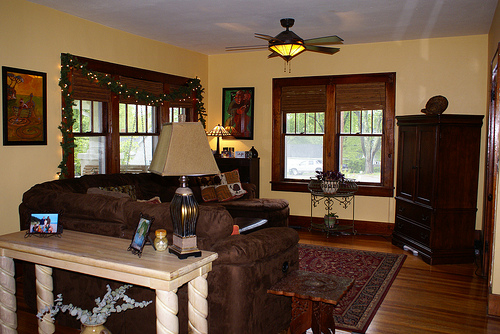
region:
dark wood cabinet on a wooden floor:
[394, 113, 483, 268]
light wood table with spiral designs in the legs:
[0, 215, 218, 332]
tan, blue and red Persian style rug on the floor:
[295, 240, 406, 331]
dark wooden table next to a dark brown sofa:
[264, 267, 355, 331]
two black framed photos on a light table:
[27, 210, 151, 257]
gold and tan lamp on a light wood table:
[148, 118, 222, 273]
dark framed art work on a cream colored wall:
[0, 62, 51, 148]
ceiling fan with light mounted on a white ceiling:
[221, 15, 345, 74]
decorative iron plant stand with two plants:
[309, 165, 358, 242]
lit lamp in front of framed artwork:
[205, 120, 232, 158]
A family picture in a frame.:
[26, 208, 65, 238]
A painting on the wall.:
[221, 85, 256, 141]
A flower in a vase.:
[36, 281, 153, 332]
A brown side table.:
[265, 265, 357, 332]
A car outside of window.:
[286, 153, 324, 177]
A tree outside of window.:
[354, 111, 381, 173]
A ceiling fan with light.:
[223, 15, 347, 72]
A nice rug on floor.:
[276, 242, 410, 332]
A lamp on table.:
[146, 120, 223, 260]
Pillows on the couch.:
[198, 166, 251, 202]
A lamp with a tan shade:
[148, 118, 219, 258]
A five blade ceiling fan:
[225, 18, 347, 71]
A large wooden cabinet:
[390, 108, 482, 268]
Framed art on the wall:
[217, 84, 257, 140]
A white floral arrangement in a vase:
[36, 282, 160, 332]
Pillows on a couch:
[193, 168, 251, 206]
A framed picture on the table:
[122, 212, 151, 255]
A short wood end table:
[265, 262, 357, 332]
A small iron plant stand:
[305, 168, 357, 246]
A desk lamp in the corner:
[205, 123, 228, 158]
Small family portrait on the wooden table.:
[117, 212, 154, 247]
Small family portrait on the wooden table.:
[81, 103, 161, 167]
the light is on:
[264, 33, 308, 68]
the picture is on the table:
[27, 208, 68, 245]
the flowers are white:
[95, 283, 127, 324]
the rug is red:
[344, 260, 363, 280]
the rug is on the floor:
[375, 270, 401, 300]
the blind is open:
[329, 75, 391, 112]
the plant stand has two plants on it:
[305, 175, 356, 240]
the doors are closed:
[403, 127, 423, 199]